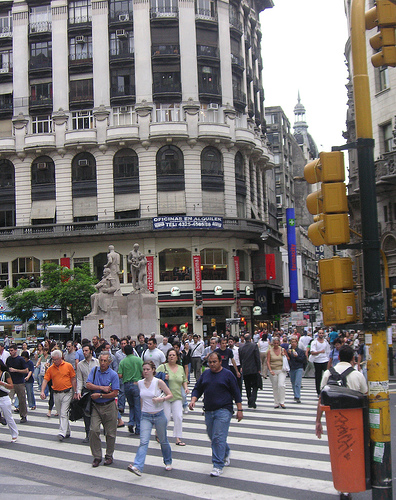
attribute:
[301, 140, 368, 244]
light — yellow, traffic, control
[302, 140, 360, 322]
light — cross, walk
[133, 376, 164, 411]
shirt — white 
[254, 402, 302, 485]
strips — wide, white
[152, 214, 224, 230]
sign — Blue 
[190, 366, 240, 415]
shirt — blue, long-sleeved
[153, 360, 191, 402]
shirt — green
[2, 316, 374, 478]
people — walking outside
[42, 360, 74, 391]
shirt — orange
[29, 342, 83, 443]
man — wearing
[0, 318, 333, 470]
people — standing outside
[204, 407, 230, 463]
jeans — blue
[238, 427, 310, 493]
lines — white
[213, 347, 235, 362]
shirt — black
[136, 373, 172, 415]
top — white, tank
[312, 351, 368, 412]
shirt — white